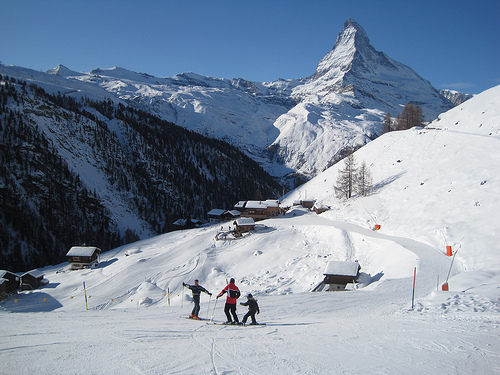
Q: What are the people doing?
A: Skiing.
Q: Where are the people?
A: On a slope.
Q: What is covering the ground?
A: Snow.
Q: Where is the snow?
A: On the ground.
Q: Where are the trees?
A: On the hills.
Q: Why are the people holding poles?
A: Speed.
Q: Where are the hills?
A: Behind the slope.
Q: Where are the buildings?
A: At the bottom of the hill.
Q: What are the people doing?
A: Skiing.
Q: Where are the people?
A: On a mountain.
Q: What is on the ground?
A: Snow.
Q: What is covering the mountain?
A: Snow.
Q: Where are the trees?
A: On the mountain on the left.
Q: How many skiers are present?
A: 3.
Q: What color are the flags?
A: Orange.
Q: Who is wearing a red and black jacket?
A: Person in center.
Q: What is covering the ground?
A: Snow.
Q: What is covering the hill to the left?
A: Trees.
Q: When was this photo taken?
A: Daytime.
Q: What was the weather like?
A: Clear.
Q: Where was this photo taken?
A: On a ski slope.